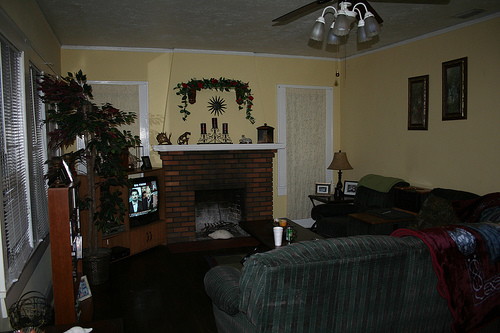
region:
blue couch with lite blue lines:
[200, 219, 499, 331]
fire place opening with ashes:
[191, 183, 253, 243]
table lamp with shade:
[325, 148, 354, 203]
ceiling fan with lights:
[265, 0, 452, 50]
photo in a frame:
[312, 181, 332, 198]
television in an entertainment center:
[122, 173, 162, 232]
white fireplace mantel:
[150, 140, 286, 155]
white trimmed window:
[272, 82, 336, 202]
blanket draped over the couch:
[387, 190, 499, 331]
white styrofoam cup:
[270, 223, 284, 249]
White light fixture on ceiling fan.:
[316, 9, 388, 46]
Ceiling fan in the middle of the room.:
[280, 6, 390, 54]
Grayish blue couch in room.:
[221, 207, 412, 281]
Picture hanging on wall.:
[436, 70, 484, 147]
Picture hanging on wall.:
[393, 69, 432, 165]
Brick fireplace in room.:
[163, 165, 304, 240]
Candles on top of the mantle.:
[198, 115, 262, 182]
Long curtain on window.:
[268, 75, 375, 252]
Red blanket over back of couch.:
[411, 215, 490, 309]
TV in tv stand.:
[124, 178, 191, 252]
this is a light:
[310, 8, 386, 54]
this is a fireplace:
[157, 137, 284, 247]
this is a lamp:
[325, 148, 356, 185]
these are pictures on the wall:
[399, 54, 485, 134]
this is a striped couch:
[216, 222, 426, 327]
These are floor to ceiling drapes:
[277, 85, 335, 217]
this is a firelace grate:
[204, 217, 236, 236]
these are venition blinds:
[4, 131, 28, 215]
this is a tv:
[131, 186, 156, 212]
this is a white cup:
[271, 226, 285, 247]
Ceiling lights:
[293, 2, 393, 54]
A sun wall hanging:
[198, 93, 240, 118]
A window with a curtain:
[275, 75, 343, 227]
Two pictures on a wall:
[386, 39, 493, 144]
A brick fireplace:
[148, 136, 279, 241]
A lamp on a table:
[323, 137, 360, 209]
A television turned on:
[111, 164, 171, 224]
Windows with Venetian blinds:
[1, 35, 58, 279]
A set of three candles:
[193, 115, 237, 151]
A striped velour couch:
[188, 212, 493, 332]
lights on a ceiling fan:
[264, 3, 398, 69]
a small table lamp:
[302, 132, 351, 206]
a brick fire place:
[152, 142, 272, 246]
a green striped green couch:
[200, 207, 497, 318]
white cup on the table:
[265, 214, 300, 254]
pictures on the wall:
[374, 49, 474, 149]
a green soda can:
[280, 217, 297, 247]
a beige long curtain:
[274, 75, 353, 235]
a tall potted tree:
[35, 65, 137, 306]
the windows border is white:
[270, 70, 387, 193]